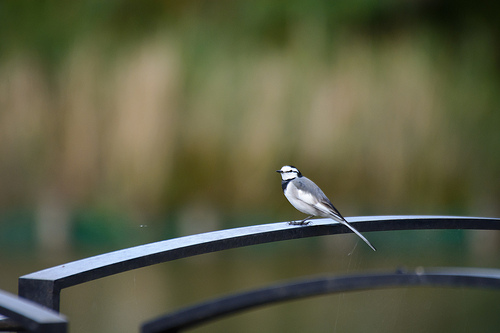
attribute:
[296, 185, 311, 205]
feathers — gray, white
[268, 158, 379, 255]
bird — perched , small, gray, white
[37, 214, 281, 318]
rails — metal , black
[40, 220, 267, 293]
rail — metal 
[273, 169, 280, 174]
beak — Small , black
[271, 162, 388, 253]
bird — standing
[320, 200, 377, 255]
tail — white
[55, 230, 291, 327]
railings — Black , metal 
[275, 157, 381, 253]
bird — small, wing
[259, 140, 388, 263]
bird — small, standing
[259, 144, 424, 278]
bird — standing outside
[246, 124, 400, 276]
bird — standing outside, small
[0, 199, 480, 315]
piece — metal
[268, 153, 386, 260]
bird — sitting , small, black , standing in daylight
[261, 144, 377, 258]
bird — black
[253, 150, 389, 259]
bird — grey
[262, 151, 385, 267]
bird — white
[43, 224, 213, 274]
fence — metal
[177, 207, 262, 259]
fence — dark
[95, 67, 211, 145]
background — blurry